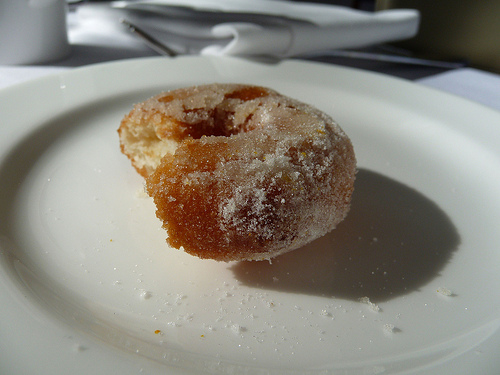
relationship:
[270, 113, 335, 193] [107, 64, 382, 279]
sugar on donut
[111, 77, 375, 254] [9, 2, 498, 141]
donut on table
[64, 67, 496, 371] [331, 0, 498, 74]
white plate on table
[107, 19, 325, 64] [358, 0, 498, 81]
fork on table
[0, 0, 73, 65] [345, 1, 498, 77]
cup on table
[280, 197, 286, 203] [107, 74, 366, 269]
sugar on dougnut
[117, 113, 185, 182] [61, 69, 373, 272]
bite out of doughnut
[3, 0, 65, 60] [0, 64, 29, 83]
cup on table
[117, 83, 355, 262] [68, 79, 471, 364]
donut covered in sugar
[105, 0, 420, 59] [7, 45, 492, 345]
napkin next plate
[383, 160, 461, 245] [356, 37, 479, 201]
shadow on plate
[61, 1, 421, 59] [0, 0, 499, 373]
napkin on plate table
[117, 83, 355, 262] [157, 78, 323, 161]
donut has some sugar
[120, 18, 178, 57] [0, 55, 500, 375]
fork next to white plate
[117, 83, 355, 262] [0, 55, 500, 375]
donut on a white plate